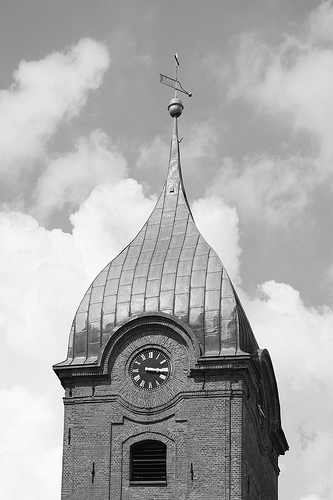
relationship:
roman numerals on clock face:
[147, 350, 156, 362] [128, 346, 175, 389]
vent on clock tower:
[128, 435, 167, 485] [55, 48, 292, 497]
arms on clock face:
[143, 364, 167, 374] [127, 345, 173, 391]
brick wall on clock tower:
[64, 380, 238, 496] [55, 48, 292, 497]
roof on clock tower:
[50, 113, 292, 453] [48, 115, 289, 498]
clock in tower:
[124, 340, 203, 401] [49, 50, 289, 498]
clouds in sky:
[5, 35, 147, 275] [1, 1, 321, 498]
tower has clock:
[49, 50, 289, 498] [124, 340, 203, 401]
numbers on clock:
[143, 347, 167, 365] [124, 340, 203, 401]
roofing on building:
[88, 167, 272, 338] [45, 308, 242, 497]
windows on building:
[113, 433, 183, 497] [45, 308, 242, 497]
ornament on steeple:
[127, 41, 221, 133] [61, 49, 279, 370]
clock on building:
[124, 340, 203, 401] [49, 225, 242, 495]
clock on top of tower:
[124, 340, 203, 401] [49, 50, 289, 498]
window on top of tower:
[126, 437, 169, 486] [49, 50, 289, 498]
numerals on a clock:
[137, 350, 162, 361] [127, 346, 172, 391]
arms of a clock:
[143, 364, 167, 374] [127, 346, 172, 391]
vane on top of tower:
[157, 49, 193, 99] [49, 50, 289, 498]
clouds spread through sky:
[5, 35, 147, 275] [1, 1, 321, 498]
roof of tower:
[50, 113, 292, 453] [49, 115, 291, 497]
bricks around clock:
[108, 326, 190, 408] [124, 340, 203, 401]